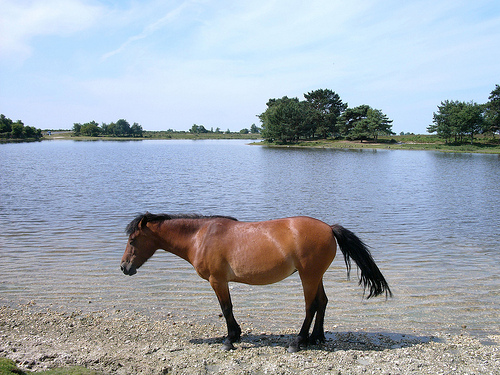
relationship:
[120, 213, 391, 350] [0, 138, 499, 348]
horse standing near water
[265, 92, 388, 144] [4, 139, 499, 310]
trees standing near lake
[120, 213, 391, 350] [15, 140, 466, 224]
horse standing next to water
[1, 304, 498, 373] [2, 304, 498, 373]
stones on ground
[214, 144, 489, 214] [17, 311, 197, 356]
water on ground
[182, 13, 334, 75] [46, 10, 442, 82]
clouds in sky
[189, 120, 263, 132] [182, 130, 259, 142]
trees on grass